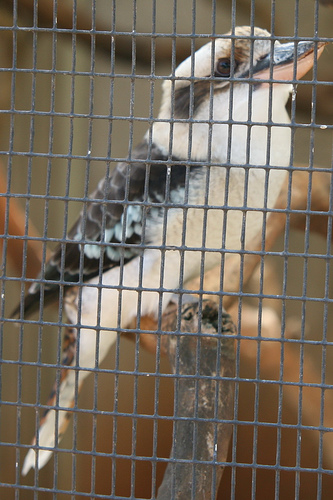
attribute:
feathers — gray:
[7, 139, 200, 321]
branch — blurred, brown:
[1, 164, 90, 304]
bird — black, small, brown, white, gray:
[15, 22, 331, 473]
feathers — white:
[15, 26, 326, 488]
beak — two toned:
[254, 43, 323, 87]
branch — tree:
[162, 292, 239, 499]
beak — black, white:
[254, 30, 328, 89]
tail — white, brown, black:
[38, 451, 51, 470]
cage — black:
[36, 44, 133, 139]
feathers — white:
[91, 46, 290, 341]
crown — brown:
[169, 40, 216, 89]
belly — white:
[195, 113, 292, 269]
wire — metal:
[90, 52, 133, 130]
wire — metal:
[101, 84, 147, 128]